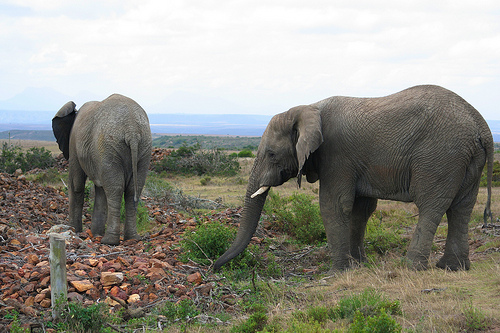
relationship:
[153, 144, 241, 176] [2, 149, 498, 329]
foilage on field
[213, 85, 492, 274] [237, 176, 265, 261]
elephant has trunk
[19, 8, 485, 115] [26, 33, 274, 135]
sky in background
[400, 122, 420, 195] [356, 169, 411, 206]
wrinkles on elephant's stomach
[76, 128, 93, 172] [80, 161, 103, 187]
wrinkles on elephant's stomach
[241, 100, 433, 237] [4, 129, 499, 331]
elephant on ground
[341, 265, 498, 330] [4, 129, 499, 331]
grass on ground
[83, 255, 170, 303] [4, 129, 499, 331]
bricks on ground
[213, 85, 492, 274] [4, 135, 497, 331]
elephant standing in grass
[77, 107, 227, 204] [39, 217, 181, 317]
elephant standing in rocks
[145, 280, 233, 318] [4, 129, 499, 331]
twigs lying on ground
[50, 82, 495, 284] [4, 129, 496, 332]
elephants standing on field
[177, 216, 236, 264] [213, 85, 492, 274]
bush near elephant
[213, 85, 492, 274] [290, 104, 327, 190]
elephant has ear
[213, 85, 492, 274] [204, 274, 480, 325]
elephant searching on ground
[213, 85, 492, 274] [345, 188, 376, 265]
elephant has leg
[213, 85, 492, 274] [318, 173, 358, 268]
elephant has leg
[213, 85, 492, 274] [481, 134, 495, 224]
elephant has tail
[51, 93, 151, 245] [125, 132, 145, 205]
elephant has tail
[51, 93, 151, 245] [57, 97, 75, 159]
elephant has ear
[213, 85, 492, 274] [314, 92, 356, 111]
elephant has bump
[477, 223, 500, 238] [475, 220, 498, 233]
pile in pile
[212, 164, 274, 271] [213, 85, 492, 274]
trunk of elephant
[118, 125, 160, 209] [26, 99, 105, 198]
tail on elephant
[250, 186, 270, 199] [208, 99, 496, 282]
left tusk of elephant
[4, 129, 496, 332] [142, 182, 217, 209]
field filled with brush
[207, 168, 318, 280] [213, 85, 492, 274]
left tusk of elephant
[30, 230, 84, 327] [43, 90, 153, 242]
post near elephant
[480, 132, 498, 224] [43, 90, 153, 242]
tail of elephant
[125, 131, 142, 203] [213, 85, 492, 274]
tail of elephant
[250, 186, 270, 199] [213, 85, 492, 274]
left tusk of elephant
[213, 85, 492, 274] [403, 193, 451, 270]
elephant has leg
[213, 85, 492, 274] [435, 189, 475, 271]
elephant has leg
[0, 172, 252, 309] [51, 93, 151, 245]
rocks are under elephant